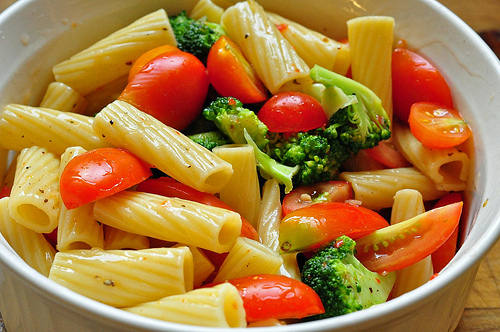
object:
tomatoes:
[126, 47, 172, 75]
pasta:
[2, 1, 469, 328]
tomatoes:
[391, 41, 452, 122]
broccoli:
[300, 233, 392, 317]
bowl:
[3, 3, 497, 330]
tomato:
[228, 271, 320, 320]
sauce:
[413, 32, 476, 78]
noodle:
[87, 190, 246, 252]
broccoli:
[274, 113, 363, 184]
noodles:
[219, 0, 313, 94]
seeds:
[358, 224, 426, 256]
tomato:
[355, 198, 465, 274]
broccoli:
[258, 132, 342, 185]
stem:
[307, 61, 379, 108]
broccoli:
[169, 14, 221, 63]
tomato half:
[261, 91, 329, 136]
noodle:
[49, 247, 196, 308]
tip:
[278, 218, 324, 257]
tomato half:
[272, 202, 391, 257]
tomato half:
[406, 99, 475, 151]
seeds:
[420, 105, 463, 133]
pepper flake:
[223, 96, 236, 108]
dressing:
[13, 42, 51, 100]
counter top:
[463, 281, 499, 331]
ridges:
[114, 114, 173, 152]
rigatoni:
[40, 80, 79, 110]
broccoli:
[311, 61, 390, 148]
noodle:
[90, 99, 231, 193]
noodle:
[1, 99, 112, 156]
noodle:
[8, 145, 65, 235]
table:
[455, 272, 484, 330]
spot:
[469, 292, 484, 309]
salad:
[67, 34, 407, 253]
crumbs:
[15, 20, 71, 40]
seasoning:
[83, 269, 122, 294]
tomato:
[58, 147, 153, 210]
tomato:
[119, 50, 209, 126]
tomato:
[205, 35, 262, 100]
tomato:
[260, 91, 326, 134]